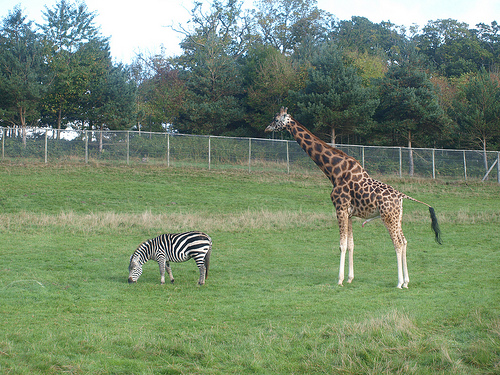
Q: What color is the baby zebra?
A: Black and white.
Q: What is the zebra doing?
A: Eating grass.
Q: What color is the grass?
A: Green.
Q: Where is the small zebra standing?
A: On the grass.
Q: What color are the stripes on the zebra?
A: Black and white.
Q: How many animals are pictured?
A: Two.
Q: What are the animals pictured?
A: Zebra and giraffe.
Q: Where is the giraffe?
A: In the field.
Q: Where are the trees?
A: Behind the fence.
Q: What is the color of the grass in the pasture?
A: Green.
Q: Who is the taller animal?
A: Giraffe.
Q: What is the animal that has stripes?
A: Zebra.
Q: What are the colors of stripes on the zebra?
A: White and black.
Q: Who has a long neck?
A: The giraffe.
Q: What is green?
A: Grass.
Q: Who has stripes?
A: The zebra.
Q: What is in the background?
A: Trees.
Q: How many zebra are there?
A: One.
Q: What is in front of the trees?
A: Fence.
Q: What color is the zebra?
A: Black and white.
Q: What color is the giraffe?
A: Brown and beige.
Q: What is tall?
A: Trees.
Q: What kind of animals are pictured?
A: A zebra and a giraffe.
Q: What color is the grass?
A: Green.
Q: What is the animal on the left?
A: Zebra.